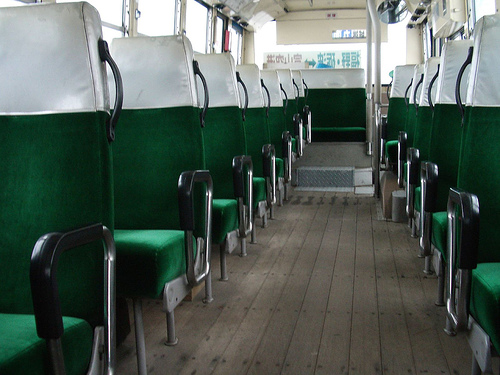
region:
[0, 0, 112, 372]
a green and white seat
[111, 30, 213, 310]
a green and white seat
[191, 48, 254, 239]
a green and white seat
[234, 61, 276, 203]
a green and white seat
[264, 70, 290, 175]
a green and white seat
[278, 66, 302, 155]
a green and white seat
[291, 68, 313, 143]
a green and white seat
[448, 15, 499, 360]
a green and white seat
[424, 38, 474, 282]
a green and white seat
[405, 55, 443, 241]
a green and white seat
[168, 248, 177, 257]
edge of a seat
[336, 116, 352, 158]
back of a seat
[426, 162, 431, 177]
part of an arm rest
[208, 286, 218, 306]
part of a pole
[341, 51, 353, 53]
part of a window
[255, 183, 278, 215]
side of a seat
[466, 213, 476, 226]
part of a chair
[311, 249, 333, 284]
part of the floor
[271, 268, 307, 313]
edge of a floor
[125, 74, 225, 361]
Tall chair with metal arms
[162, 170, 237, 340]
Metal arms on seat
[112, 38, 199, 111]
A white top of seat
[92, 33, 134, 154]
A black plastic handle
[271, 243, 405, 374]
A wooden floor plank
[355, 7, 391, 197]
A tall metal pole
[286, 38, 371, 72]
A glass windshield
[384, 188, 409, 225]
A round metal canister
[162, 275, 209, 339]
Metal legs on a seat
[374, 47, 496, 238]
A row of green and white seats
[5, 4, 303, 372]
row of bus seats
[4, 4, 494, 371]
two rows of bus seats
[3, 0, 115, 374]
green and white bus seat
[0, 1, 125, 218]
handle of bus seat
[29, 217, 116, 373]
arm rest of bus seat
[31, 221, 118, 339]
black and metal of arm rest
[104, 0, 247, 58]
row of bus windows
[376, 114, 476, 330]
row of seat arm rests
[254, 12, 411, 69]
windshield in front of bus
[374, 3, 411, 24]
reflection on round mirror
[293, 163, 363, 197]
white grate on back of bus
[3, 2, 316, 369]
row of green and white aisle seating on bus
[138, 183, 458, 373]
tan raw hardwood floors in bus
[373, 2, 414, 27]
drivers mirror mounted on ceiling of bus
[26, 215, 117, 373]
black arm rest of green and white chair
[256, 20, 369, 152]
green and white back seat of bus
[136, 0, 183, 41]
side bus window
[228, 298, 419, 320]
line of nails in hardwood floors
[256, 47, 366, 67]
buildings through back window of bus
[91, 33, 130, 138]
top seat handle on bus green and white seat